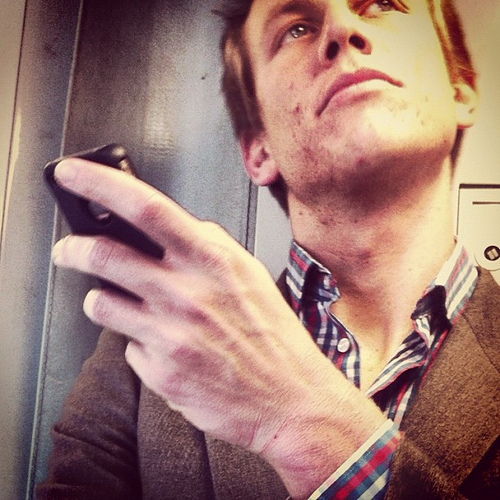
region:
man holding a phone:
[37, 0, 498, 440]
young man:
[205, 0, 486, 215]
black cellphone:
[38, 140, 164, 276]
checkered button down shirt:
[272, 227, 482, 430]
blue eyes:
[257, 0, 424, 45]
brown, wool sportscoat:
[32, 266, 497, 497]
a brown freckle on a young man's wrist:
[266, 431, 281, 441]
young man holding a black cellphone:
[41, 0, 496, 498]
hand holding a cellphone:
[30, 137, 325, 447]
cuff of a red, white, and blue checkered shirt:
[280, 418, 400, 498]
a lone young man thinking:
[202, 1, 487, 218]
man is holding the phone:
[31, 32, 459, 496]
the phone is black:
[13, 124, 213, 352]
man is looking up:
[234, 2, 486, 310]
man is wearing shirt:
[275, 240, 482, 493]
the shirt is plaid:
[292, 252, 479, 467]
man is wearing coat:
[44, 316, 156, 491]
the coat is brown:
[58, 362, 248, 472]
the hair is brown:
[200, 45, 268, 143]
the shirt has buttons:
[303, 250, 380, 400]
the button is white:
[318, 327, 376, 379]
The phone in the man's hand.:
[37, 151, 169, 260]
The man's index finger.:
[54, 153, 201, 245]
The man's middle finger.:
[43, 222, 181, 305]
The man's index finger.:
[74, 284, 154, 333]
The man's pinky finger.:
[114, 335, 164, 383]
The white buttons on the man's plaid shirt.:
[318, 267, 355, 371]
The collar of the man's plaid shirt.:
[278, 235, 476, 335]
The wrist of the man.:
[264, 395, 386, 497]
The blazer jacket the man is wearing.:
[79, 274, 497, 494]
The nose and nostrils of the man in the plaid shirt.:
[312, 19, 375, 59]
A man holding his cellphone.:
[61, 118, 201, 280]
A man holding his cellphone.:
[65, 183, 212, 331]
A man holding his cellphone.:
[35, 114, 172, 364]